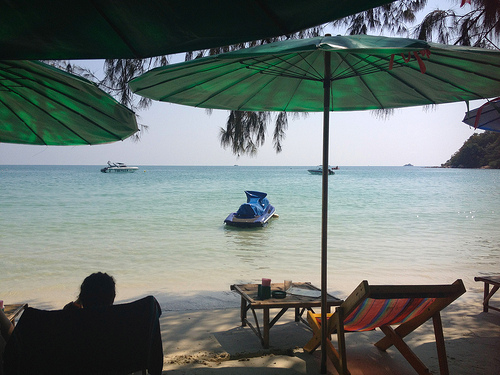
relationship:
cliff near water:
[448, 101, 498, 166] [7, 168, 222, 275]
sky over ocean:
[165, 103, 337, 173] [94, 163, 481, 278]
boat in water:
[224, 190, 279, 227] [3, 160, 498, 295]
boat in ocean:
[224, 190, 279, 227] [3, 164, 493, 259]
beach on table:
[125, 305, 497, 373] [231, 276, 344, 346]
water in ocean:
[3, 160, 498, 295] [0, 165, 494, 314]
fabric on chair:
[351, 294, 432, 333] [292, 268, 469, 373]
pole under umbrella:
[314, 87, 341, 277] [170, 30, 494, 120]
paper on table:
[285, 284, 323, 299] [233, 277, 343, 352]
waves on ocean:
[342, 164, 497, 244] [0, 165, 494, 314]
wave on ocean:
[27, 189, 117, 233] [0, 165, 494, 314]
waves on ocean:
[358, 164, 464, 263] [0, 165, 494, 314]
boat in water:
[224, 187, 277, 229] [4, 164, 497, 372]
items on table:
[255, 277, 322, 298] [229, 282, 344, 347]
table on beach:
[229, 278, 344, 350] [0, 289, 498, 374]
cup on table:
[255, 281, 272, 301] [229, 267, 346, 351]